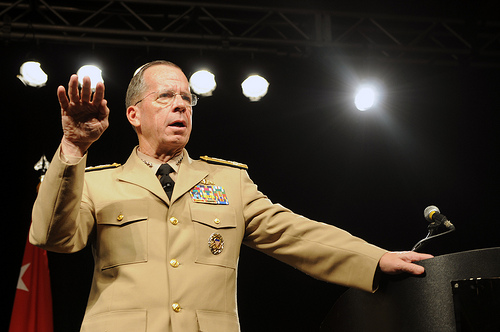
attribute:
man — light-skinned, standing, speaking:
[28, 59, 435, 331]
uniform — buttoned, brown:
[28, 143, 389, 331]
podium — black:
[389, 245, 499, 331]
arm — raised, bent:
[28, 73, 110, 252]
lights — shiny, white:
[20, 58, 380, 112]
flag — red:
[8, 179, 55, 332]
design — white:
[15, 263, 30, 292]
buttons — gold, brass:
[113, 213, 221, 312]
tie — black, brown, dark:
[158, 163, 176, 201]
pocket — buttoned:
[189, 203, 238, 270]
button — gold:
[214, 218, 221, 223]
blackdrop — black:
[0, 0, 498, 332]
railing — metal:
[0, 0, 499, 72]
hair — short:
[125, 59, 179, 108]